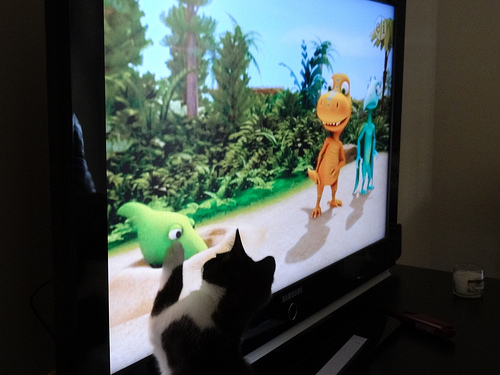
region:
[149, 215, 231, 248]
black and white eyes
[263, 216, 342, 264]
shadow of animal on sand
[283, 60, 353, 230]
large orange animal standing up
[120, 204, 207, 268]
lime green animal stuck in sand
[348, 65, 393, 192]
sad face on blue animal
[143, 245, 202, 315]
cat's black and white paws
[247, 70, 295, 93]
top of red building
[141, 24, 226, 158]
tall tan base of tree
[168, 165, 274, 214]
green plant at side of grass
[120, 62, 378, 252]
colorful animals on the sand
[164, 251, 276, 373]
the cat is black and white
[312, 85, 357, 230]
the dragon is orange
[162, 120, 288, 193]
the grass is green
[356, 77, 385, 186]
the bird is green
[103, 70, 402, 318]
the tv is on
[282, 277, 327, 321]
the make is a samsung one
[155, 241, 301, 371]
the paws are on th etv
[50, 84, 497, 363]
the photo was taken outdoors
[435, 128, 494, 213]
the wall is white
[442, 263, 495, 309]
the candle is on the counter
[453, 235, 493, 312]
White candle in a jar.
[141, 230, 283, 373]
Cat with paws in t.v.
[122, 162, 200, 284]
Green fish digging in sand.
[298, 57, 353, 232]
Orange cartoon dinosaur on t.v.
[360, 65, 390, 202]
Blue cartoon dinosaur on t.v.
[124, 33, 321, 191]
Green tree and trunk.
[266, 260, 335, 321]
Samsung t.v. with cartoons on it.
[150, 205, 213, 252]
Eyes on a cartoon fish.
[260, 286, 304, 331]
Power button for a t.v.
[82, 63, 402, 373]
A cat watching cartoons on t.v.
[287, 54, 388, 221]
dinosaurs on the screen of a TV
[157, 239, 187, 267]
a cat paw on a tv screen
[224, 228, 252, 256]
an ear of a cat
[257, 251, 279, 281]
an ear of a cat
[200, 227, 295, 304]
a head of a cat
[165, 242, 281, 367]
a black and white cat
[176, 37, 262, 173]
the jungle of a cartoon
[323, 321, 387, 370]
the stand of a tv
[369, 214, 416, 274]
a corner of a tv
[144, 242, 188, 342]
a leg of a cat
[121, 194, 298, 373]
a kitten in front of TV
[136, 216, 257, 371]
Black and white kitten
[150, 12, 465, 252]
cartoon showing on TV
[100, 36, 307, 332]
A green blob on TV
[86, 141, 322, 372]
Black and white cat looking at the TV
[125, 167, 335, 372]
Black and white cat blocking the TV screen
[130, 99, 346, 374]
cat pawing at the TV screen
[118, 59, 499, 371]
big TV in the living room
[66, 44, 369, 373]
black and white cat with one paw on TV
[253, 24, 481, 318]
Orange dinosaur on TV